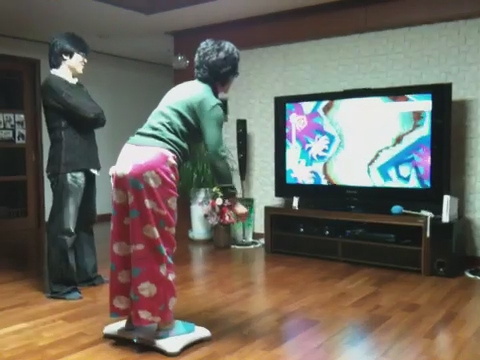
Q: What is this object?
A: Entertainment center.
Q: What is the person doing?
A: Playing a game.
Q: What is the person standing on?
A: Balance board.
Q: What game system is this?
A: Wii.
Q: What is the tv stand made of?
A: Glass.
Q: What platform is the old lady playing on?
A: Wii.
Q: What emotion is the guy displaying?
A: Happiness.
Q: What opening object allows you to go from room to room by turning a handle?
A: Door.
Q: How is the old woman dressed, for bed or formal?
A: For bed.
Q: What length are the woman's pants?
A: Full length.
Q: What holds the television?
A: Stand.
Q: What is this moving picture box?
A: Television.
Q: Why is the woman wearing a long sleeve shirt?
A: She's cold.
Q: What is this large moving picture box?
A: Tv.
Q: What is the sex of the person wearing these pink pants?
A: Female.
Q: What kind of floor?
A: Hardwood.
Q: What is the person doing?
A: Playing a game.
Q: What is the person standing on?
A: Balance board.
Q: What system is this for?
A: Nintendo wii.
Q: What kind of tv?
A: Flatscreen.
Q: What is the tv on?
A: Television stand.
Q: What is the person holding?
A: Controller.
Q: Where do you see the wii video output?
A: TV.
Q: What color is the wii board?
A: White.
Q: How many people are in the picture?
A: Two.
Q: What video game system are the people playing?
A: Wii.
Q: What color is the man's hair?
A: Black.